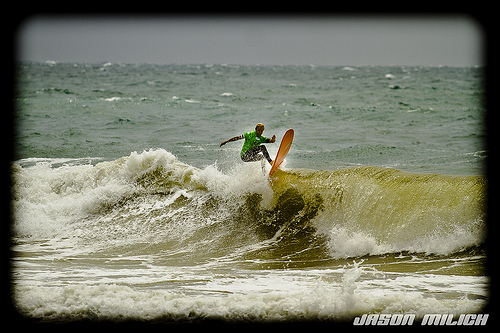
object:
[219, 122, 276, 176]
man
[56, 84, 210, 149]
water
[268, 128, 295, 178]
board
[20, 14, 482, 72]
sky